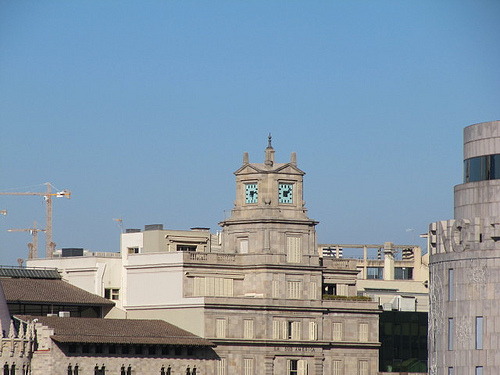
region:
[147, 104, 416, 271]
an outside clock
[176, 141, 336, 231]
an outside clock on building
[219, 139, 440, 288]
two blue clocks on building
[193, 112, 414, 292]
two blue clocks on the building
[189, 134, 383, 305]
blue clocks on old building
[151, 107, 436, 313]
an old building with clocks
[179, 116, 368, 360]
an old building with blue clocks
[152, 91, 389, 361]
an old building with tower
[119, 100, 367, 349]
a building with an old clock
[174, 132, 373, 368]
tower with blue clock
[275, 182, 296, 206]
square clock on tower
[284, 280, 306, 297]
square window on tower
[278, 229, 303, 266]
square window on tower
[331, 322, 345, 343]
square window on tower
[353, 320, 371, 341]
square window on tower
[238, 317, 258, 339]
square window on tower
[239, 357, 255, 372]
square window on tower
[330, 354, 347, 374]
square window on tower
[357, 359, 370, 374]
square window on tower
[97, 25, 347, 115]
the sky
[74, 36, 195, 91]
the sky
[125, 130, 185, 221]
the sky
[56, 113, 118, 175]
the sky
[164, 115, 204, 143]
the sky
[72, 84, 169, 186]
the sky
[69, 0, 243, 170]
the sky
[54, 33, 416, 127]
Sky is blue color.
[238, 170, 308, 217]
Tower has two face of clock.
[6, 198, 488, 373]
Buildings are grey color.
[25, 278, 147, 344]
Roof is brown color.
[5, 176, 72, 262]
Crane is seen in the left side of the picture.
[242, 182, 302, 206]
Clock is blue and black color.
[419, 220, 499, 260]
Letters are made of brick.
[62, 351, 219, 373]
Windows are attached to the building wall.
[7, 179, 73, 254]
Crane is red and white color.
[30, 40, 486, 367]
Day time picture.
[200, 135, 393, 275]
two outside clocks on building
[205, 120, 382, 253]
two bue outside clocks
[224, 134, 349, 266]
blue outside clocks on building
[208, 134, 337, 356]
outside clocks on top of building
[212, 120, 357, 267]
blue clocks on top of building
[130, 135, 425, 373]
a tall building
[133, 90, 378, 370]
a tall building with clocks